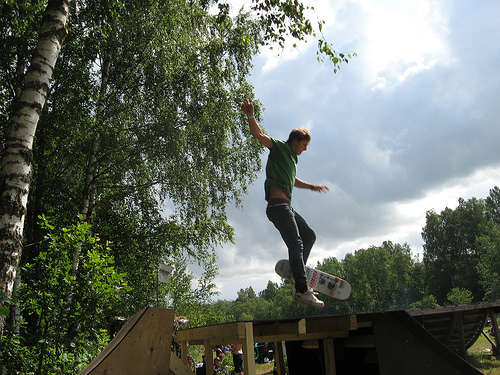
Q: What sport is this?
A: Skateboarding.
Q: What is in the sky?
A: Clouds.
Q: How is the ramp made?
A: Made of wood.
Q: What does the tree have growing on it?
A: Moss.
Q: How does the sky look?
A: Cloudy.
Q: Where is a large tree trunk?
A: Left side.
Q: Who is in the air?
A: Skateboarder.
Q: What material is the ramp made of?
A: Wood.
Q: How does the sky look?
A: Dark clouds.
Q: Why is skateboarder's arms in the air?
A: For balance.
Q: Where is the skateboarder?
A: In the air.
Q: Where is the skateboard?
A: In the air.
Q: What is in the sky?
A: Clouds.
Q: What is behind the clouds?
A: The sky.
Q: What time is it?
A: Afternoon.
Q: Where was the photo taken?
A: Outside somewhere.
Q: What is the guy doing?
A: Skating.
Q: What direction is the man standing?
A: Straight up.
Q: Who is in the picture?
A: A skateboarder.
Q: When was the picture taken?
A: Daytime.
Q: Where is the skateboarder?
A: At a skatepark.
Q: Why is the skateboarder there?
A: To ride a skateboard.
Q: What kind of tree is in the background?
A: Birch.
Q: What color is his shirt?
A: Green.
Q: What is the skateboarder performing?
A: A trick.